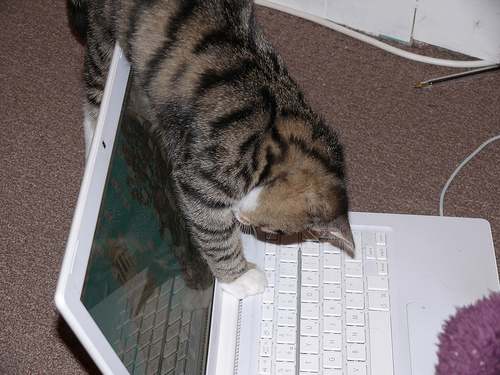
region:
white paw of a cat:
[203, 244, 277, 316]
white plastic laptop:
[33, 36, 498, 368]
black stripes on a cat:
[139, 9, 238, 119]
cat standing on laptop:
[60, 2, 374, 308]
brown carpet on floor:
[329, 79, 431, 159]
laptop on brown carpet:
[29, 42, 404, 372]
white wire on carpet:
[271, 0, 498, 89]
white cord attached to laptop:
[431, 123, 498, 262]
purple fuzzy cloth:
[425, 283, 493, 372]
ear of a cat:
[316, 195, 363, 257]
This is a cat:
[78, 10, 380, 261]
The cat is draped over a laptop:
[85, 34, 364, 247]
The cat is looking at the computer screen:
[207, 113, 398, 290]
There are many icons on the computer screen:
[92, 201, 205, 356]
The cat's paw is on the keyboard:
[216, 245, 304, 312]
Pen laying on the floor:
[410, 60, 499, 95]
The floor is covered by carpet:
[349, 90, 456, 170]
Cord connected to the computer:
[436, 121, 498, 221]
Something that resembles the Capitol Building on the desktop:
[85, 233, 215, 373]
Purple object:
[437, 293, 498, 370]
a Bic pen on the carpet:
[405, 60, 495, 90]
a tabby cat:
[77, 0, 352, 291]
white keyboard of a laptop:
[268, 236, 391, 371]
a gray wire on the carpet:
[430, 106, 495, 209]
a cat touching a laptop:
[63, 6, 363, 306]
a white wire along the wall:
[275, 6, 395, 37]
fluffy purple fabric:
[433, 285, 494, 371]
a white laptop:
[55, 70, 490, 366]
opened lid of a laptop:
[60, 45, 215, 371]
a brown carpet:
[348, 67, 403, 142]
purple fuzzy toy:
[415, 255, 497, 373]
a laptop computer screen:
[40, 52, 320, 373]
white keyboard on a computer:
[237, 187, 397, 373]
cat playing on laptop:
[39, 0, 406, 301]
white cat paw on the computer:
[198, 235, 286, 349]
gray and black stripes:
[181, 27, 296, 132]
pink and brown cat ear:
[296, 154, 376, 291]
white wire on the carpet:
[408, 141, 495, 225]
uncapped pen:
[403, 47, 498, 97]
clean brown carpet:
[13, 113, 62, 214]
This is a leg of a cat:
[160, 126, 276, 311]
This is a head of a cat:
[221, 100, 381, 265]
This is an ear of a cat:
[300, 201, 372, 258]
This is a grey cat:
[57, 5, 365, 309]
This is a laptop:
[52, 35, 496, 373]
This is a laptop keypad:
[242, 181, 404, 371]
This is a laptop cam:
[88, 125, 113, 157]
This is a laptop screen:
[32, 48, 223, 373]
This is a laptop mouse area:
[400, 285, 498, 373]